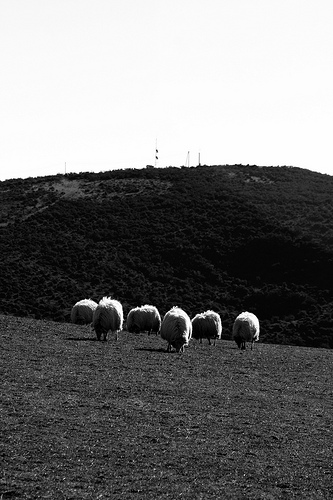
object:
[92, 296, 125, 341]
sheep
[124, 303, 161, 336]
sheep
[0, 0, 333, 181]
sky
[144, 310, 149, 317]
white fur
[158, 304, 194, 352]
sheep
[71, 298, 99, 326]
sheep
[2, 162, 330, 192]
hilltop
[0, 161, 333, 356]
vegetation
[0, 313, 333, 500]
ground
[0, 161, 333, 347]
hill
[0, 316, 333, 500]
grass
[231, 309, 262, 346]
sheep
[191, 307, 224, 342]
sheep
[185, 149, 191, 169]
pole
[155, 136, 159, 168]
pole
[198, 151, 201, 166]
pole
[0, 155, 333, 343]
mountain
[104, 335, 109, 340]
feet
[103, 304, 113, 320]
fur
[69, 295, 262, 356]
group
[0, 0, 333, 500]
photo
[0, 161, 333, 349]
formation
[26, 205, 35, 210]
spot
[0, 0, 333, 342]
background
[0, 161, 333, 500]
field